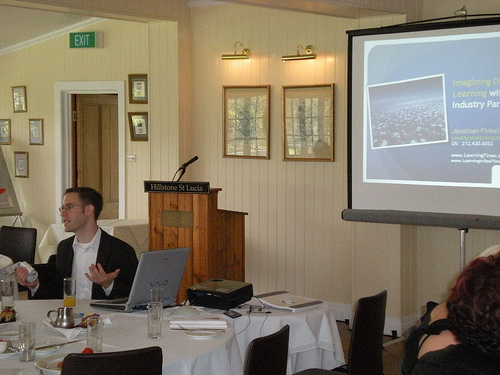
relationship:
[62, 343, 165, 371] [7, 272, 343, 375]
chair at table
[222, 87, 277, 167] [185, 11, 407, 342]
picture on wall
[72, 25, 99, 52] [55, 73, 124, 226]
sign above door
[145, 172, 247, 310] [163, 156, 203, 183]
podium has microphone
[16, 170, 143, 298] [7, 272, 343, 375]
man at table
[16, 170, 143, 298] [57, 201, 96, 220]
man wearing glasses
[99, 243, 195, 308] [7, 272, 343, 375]
laptop on table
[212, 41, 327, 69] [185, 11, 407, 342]
light fixtures on wall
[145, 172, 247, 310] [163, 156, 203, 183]
podium with microphone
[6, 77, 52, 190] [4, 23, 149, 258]
pictures on wall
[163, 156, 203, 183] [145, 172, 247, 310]
microphone on podium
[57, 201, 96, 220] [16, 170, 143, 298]
glasses on man